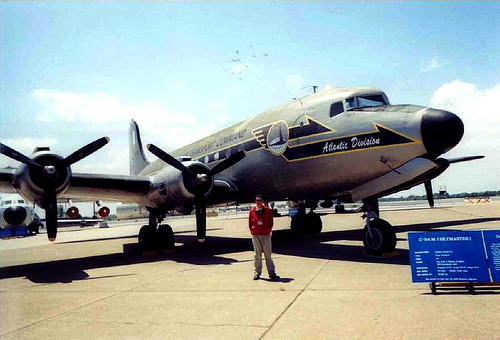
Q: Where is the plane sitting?
A: Ground.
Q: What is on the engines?
A: Propellers.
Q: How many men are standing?
A: One.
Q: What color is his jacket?
A: Red.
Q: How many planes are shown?
A: Two.